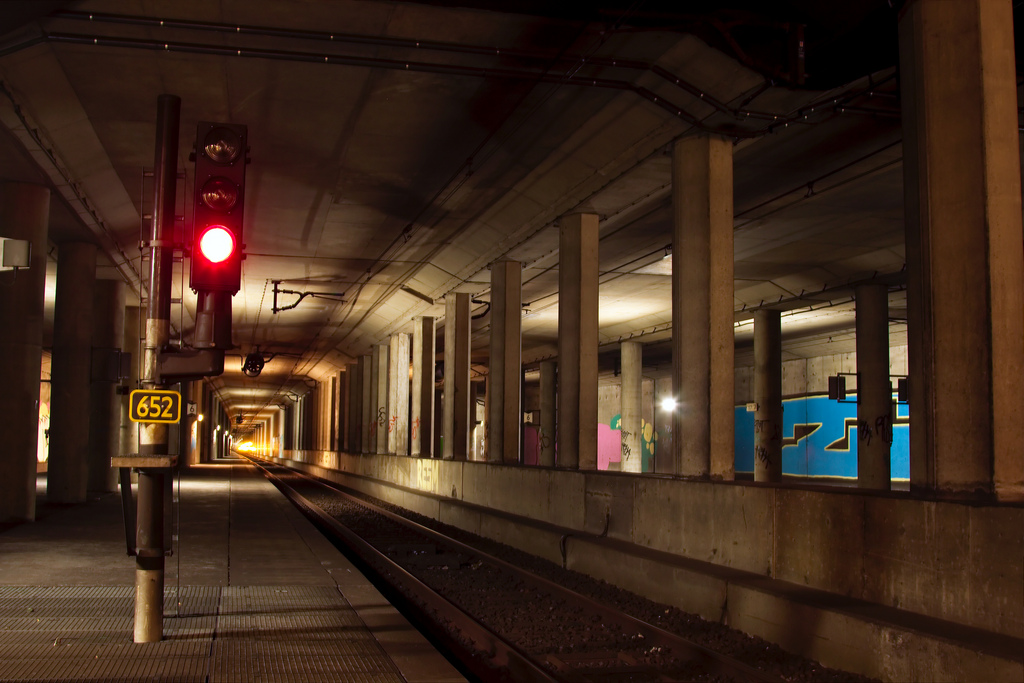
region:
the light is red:
[195, 215, 247, 277]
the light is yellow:
[231, 432, 270, 459]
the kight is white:
[650, 383, 683, 418]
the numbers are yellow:
[120, 382, 193, 430]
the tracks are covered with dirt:
[464, 570, 512, 619]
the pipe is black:
[351, 42, 453, 87]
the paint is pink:
[597, 420, 618, 466]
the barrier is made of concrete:
[688, 493, 838, 605]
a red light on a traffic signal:
[187, 119, 249, 296]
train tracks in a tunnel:
[217, 388, 611, 680]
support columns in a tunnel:
[283, 119, 775, 493]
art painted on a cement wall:
[687, 375, 922, 486]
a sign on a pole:
[125, 388, 182, 502]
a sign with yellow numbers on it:
[122, 388, 181, 430]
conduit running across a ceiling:
[64, 9, 641, 107]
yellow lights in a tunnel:
[215, 414, 274, 457]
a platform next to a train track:
[188, 448, 357, 660]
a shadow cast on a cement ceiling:
[244, 108, 441, 236]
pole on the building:
[988, 399, 1008, 434]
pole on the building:
[706, 385, 741, 469]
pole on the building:
[552, 383, 606, 464]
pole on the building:
[465, 373, 517, 453]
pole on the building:
[327, 391, 367, 446]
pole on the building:
[390, 389, 479, 446]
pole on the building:
[855, 414, 887, 471]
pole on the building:
[748, 386, 775, 463]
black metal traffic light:
[187, 117, 242, 296]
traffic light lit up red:
[198, 225, 236, 264]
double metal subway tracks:
[234, 446, 852, 680]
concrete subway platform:
[0, 449, 469, 680]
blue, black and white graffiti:
[727, 379, 917, 482]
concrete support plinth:
[2, 190, 51, 533]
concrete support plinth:
[44, 240, 98, 506]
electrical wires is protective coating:
[0, 2, 908, 149]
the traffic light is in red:
[181, 109, 260, 315]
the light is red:
[187, 214, 243, 278]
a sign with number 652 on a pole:
[117, 372, 195, 440]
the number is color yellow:
[123, 382, 191, 428]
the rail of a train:
[249, 454, 691, 658]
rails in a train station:
[15, 23, 964, 680]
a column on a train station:
[842, 263, 904, 491]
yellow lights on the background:
[210, 411, 286, 465]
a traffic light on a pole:
[115, 68, 267, 664]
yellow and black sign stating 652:
[107, 363, 205, 434]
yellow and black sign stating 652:
[106, 358, 212, 448]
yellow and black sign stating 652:
[112, 369, 202, 427]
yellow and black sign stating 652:
[118, 369, 208, 446]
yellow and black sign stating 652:
[118, 375, 214, 446]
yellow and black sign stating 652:
[119, 379, 212, 444]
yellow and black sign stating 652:
[112, 373, 212, 450]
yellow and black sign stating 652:
[119, 376, 217, 454]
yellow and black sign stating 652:
[119, 376, 200, 443]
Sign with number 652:
[128, 385, 187, 428]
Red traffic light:
[190, 220, 244, 272]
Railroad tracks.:
[255, 461, 753, 676]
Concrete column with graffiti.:
[613, 335, 652, 471]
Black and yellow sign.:
[128, 379, 185, 431]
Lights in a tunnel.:
[231, 433, 280, 462]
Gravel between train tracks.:
[455, 594, 620, 640]